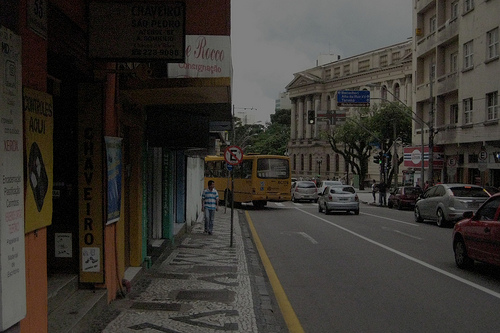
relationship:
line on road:
[250, 228, 311, 331] [261, 208, 380, 322]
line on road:
[242, 200, 310, 332] [261, 208, 380, 322]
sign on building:
[214, 138, 281, 195] [364, 20, 482, 149]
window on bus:
[455, 43, 472, 80] [236, 136, 318, 254]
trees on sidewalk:
[343, 108, 465, 195] [319, 143, 478, 241]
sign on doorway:
[15, 112, 114, 227] [36, 74, 143, 328]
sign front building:
[214, 138, 281, 195] [73, 5, 196, 275]